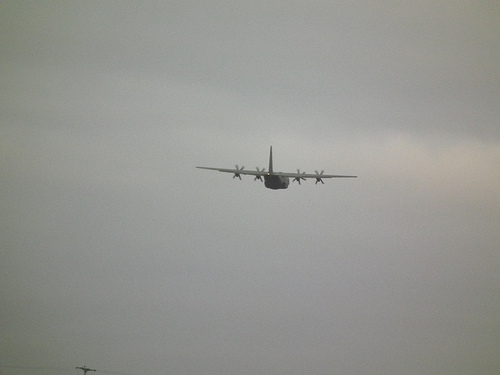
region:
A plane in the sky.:
[195, 148, 356, 192]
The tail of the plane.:
[266, 146, 276, 173]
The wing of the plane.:
[194, 155, 265, 185]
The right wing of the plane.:
[291, 169, 356, 184]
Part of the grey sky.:
[128, 275, 212, 308]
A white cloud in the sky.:
[351, 126, 495, 188]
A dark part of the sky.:
[7, 9, 43, 61]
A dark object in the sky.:
[72, 365, 96, 374]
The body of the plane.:
[264, 175, 289, 190]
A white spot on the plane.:
[266, 172, 271, 177]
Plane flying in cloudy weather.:
[72, 364, 100, 373]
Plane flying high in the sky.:
[196, 144, 362, 190]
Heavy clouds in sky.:
[52, 29, 311, 134]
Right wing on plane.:
[287, 168, 360, 184]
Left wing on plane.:
[192, 162, 264, 181]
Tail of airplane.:
[266, 147, 275, 174]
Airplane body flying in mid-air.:
[265, 177, 290, 189]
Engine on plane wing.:
[314, 169, 326, 185]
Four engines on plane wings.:
[228, 166, 324, 186]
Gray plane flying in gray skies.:
[190, 144, 357, 194]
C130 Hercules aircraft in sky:
[199, 133, 353, 208]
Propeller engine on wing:
[230, 163, 247, 187]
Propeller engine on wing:
[247, 170, 271, 187]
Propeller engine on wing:
[294, 167, 304, 187]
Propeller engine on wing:
[313, 171, 328, 189]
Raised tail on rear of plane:
[263, 140, 298, 178]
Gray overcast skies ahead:
[80, 73, 496, 276]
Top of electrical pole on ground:
[76, 361, 108, 373]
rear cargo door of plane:
[261, 177, 281, 192]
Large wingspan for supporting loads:
[213, 163, 356, 180]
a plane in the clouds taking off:
[193, 145, 365, 190]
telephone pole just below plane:
[58, 353, 120, 373]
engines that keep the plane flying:
[223, 161, 264, 186]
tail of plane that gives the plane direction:
[264, 140, 276, 185]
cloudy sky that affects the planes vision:
[4, 7, 495, 46]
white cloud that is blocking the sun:
[368, 127, 498, 187]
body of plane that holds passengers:
[263, 175, 290, 191]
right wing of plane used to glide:
[284, 165, 359, 187]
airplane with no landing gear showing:
[188, 144, 364, 192]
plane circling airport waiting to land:
[178, 144, 369, 192]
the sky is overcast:
[10, 12, 477, 337]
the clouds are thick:
[43, 9, 463, 313]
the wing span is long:
[178, 152, 362, 190]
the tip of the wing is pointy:
[282, 159, 362, 183]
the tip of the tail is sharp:
[255, 135, 290, 160]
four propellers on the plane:
[218, 162, 338, 189]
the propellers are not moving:
[280, 161, 327, 193]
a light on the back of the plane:
[257, 167, 280, 182]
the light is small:
[260, 167, 279, 179]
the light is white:
[259, 168, 275, 178]